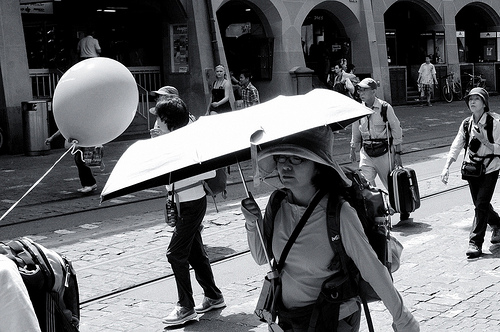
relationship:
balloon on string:
[41, 54, 152, 151] [2, 137, 79, 227]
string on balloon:
[2, 137, 79, 227] [41, 54, 152, 151]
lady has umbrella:
[249, 149, 385, 325] [111, 87, 351, 269]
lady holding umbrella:
[249, 149, 385, 325] [111, 87, 351, 269]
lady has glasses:
[249, 149, 385, 325] [272, 150, 308, 171]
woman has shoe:
[439, 77, 499, 244] [464, 236, 485, 258]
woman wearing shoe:
[439, 77, 499, 244] [487, 220, 500, 243]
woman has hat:
[439, 77, 499, 244] [461, 82, 493, 114]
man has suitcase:
[334, 69, 394, 195] [379, 163, 422, 220]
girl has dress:
[204, 62, 236, 113] [205, 85, 235, 112]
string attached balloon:
[2, 137, 79, 227] [41, 54, 152, 151]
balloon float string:
[41, 54, 152, 151] [2, 137, 79, 227]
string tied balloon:
[2, 137, 79, 227] [41, 54, 152, 151]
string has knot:
[2, 137, 79, 227] [70, 141, 79, 147]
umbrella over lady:
[111, 87, 351, 269] [249, 149, 385, 325]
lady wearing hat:
[249, 149, 385, 325] [258, 122, 360, 190]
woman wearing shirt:
[439, 77, 499, 244] [452, 113, 499, 195]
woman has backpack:
[439, 77, 499, 244] [457, 111, 500, 131]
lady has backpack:
[249, 149, 385, 325] [261, 184, 405, 270]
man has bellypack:
[334, 69, 394, 195] [353, 134, 399, 154]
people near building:
[106, 46, 488, 134] [3, 3, 496, 104]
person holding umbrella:
[249, 149, 385, 325] [111, 87, 351, 269]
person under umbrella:
[249, 149, 385, 325] [111, 87, 351, 269]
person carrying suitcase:
[334, 69, 394, 195] [379, 163, 422, 220]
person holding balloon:
[0, 252, 88, 330] [41, 54, 152, 151]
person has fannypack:
[351, 75, 407, 182] [353, 134, 399, 154]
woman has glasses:
[249, 149, 385, 325] [272, 150, 308, 171]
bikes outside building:
[438, 68, 492, 102] [3, 3, 496, 104]